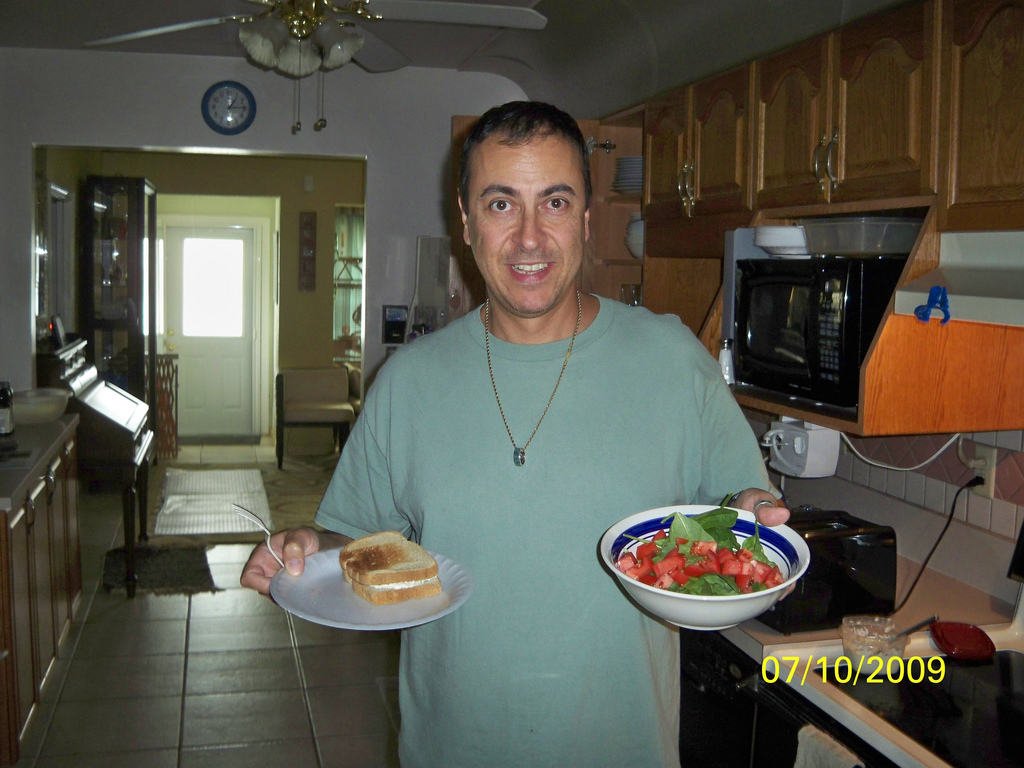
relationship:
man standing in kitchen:
[239, 101, 792, 767] [7, 19, 1019, 763]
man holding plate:
[239, 101, 792, 767] [261, 520, 476, 639]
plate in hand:
[261, 520, 476, 639] [205, 492, 363, 592]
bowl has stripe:
[596, 484, 823, 640] [609, 492, 804, 599]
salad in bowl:
[594, 510, 789, 601] [596, 484, 823, 640]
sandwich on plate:
[335, 525, 450, 610] [261, 527, 480, 648]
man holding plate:
[296, 80, 800, 763] [261, 503, 469, 651]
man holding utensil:
[296, 80, 800, 763] [238, 467, 308, 573]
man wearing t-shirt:
[296, 80, 800, 763] [331, 253, 781, 763]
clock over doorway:
[197, 56, 267, 149] [11, 110, 400, 521]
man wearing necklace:
[296, 80, 800, 763] [467, 276, 588, 473]